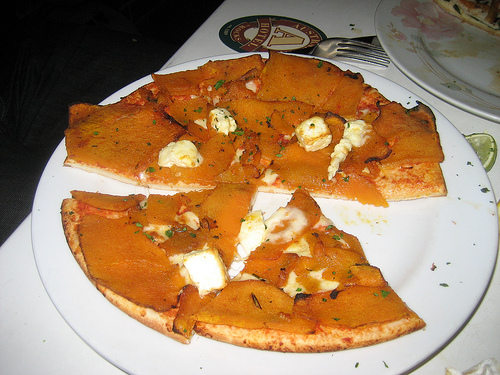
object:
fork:
[286, 35, 391, 67]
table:
[2, 1, 499, 374]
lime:
[464, 133, 496, 171]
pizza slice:
[195, 187, 425, 353]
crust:
[197, 312, 428, 352]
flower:
[399, 3, 466, 39]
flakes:
[426, 260, 442, 273]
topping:
[77, 214, 186, 311]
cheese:
[157, 140, 204, 170]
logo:
[217, 15, 326, 54]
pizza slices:
[59, 184, 257, 347]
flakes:
[273, 151, 283, 159]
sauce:
[398, 172, 421, 191]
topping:
[183, 244, 233, 296]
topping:
[370, 285, 388, 300]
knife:
[349, 35, 381, 47]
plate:
[32, 52, 500, 374]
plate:
[370, 0, 499, 127]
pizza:
[62, 53, 452, 358]